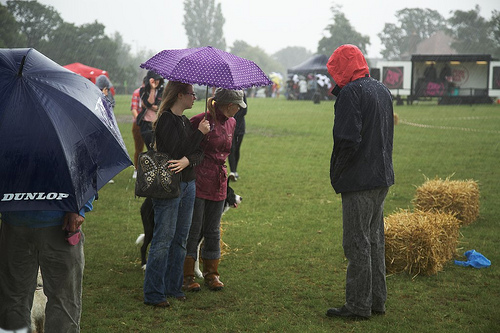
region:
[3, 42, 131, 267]
Umbrella letters advertise Dunlop.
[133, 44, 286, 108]
Purple umbrella polka dot.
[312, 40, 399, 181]
Red hoodie for rainwear.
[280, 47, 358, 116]
Background festival tent wet.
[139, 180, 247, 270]
Pet dog behind women.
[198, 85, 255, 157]
Has tan visor cap.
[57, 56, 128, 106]
Barely seen red tent.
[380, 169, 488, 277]
Hay bales feed animals.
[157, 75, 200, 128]
She wears her eyeglasses.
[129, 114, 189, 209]
Handbag shape of butterfly.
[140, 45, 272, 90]
purple with white poka dots umbrella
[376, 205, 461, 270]
bale of hay on field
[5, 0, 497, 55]
gray hazy sky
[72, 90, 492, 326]
large green grass field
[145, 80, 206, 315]
woman carrying shoulder bag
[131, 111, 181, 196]
black shoulder bag with butterfly design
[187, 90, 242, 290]
lady holding purple umbrella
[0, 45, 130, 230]
navy blue umbrella with white logo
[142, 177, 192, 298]
dark blue jeans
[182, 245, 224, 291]
brown winter boots with fur trim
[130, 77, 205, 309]
person holding a purse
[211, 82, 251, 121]
hat on a persons head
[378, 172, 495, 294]
two straw bales on grass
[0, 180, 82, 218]
a logo on an umbrella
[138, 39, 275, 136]
purple umbrella in a woman's hand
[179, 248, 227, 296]
two boots on feet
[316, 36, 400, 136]
person with a red hood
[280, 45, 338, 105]
people under a tent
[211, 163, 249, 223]
dog's head near a person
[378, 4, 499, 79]
trees behind a stage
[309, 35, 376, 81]
the hood is red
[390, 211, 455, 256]
the hay is brown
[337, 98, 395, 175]
the top is black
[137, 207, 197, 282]
the jeans are green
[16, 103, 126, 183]
the umbrella is blue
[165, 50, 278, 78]
the umbrella has dots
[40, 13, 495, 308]
it is raining outside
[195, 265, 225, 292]
the boots are brown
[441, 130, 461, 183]
the grass is green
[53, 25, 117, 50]
the trees are green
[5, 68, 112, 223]
navy blue Dunlop umbrella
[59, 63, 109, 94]
Bright red umbrella with white dots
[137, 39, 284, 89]
large purple umbrella with white polka dots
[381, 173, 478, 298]
two large bales of hay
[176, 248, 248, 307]
one pair mid calf leather boots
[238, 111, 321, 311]
large dark green grassy lot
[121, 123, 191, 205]
large shoulder bag with large crafted butterfly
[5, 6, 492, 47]
large trees full of green leaves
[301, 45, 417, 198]
navy parka with a red hat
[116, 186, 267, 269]
large black and white dog on leash